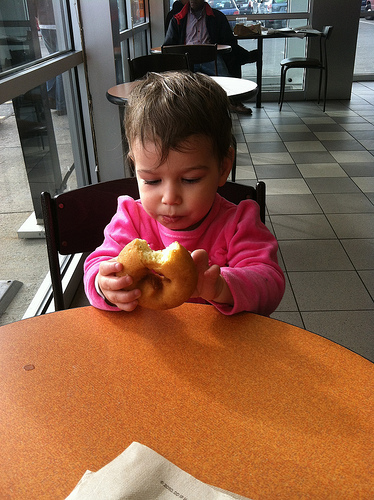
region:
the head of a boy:
[116, 88, 253, 234]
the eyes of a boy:
[135, 160, 234, 184]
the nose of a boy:
[160, 186, 188, 212]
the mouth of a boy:
[149, 206, 201, 229]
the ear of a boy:
[208, 116, 256, 197]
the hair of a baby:
[104, 4, 241, 225]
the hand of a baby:
[84, 241, 151, 320]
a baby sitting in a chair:
[74, 110, 348, 380]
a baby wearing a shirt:
[79, 125, 314, 345]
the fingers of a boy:
[95, 252, 152, 321]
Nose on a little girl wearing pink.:
[159, 177, 180, 206]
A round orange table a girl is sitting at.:
[1, 299, 373, 498]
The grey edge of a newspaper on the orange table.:
[63, 440, 247, 498]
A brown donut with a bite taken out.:
[112, 239, 195, 308]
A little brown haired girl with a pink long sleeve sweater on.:
[83, 72, 284, 317]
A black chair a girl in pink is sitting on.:
[39, 178, 266, 309]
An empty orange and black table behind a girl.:
[106, 74, 258, 106]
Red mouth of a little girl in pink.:
[157, 211, 185, 222]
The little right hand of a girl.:
[96, 259, 140, 313]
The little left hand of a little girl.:
[184, 248, 220, 299]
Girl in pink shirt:
[75, 60, 288, 322]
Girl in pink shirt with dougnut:
[76, 65, 280, 317]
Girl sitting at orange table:
[29, 65, 303, 357]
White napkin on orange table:
[54, 418, 262, 498]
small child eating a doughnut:
[77, 155, 236, 342]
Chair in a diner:
[270, 10, 344, 116]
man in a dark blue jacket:
[133, 1, 257, 62]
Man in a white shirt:
[158, 1, 238, 70]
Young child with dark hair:
[109, 67, 249, 236]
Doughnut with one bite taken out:
[103, 232, 204, 319]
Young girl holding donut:
[86, 69, 287, 317]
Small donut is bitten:
[113, 236, 193, 312]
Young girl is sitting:
[85, 71, 286, 316]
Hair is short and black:
[126, 68, 237, 180]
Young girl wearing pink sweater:
[81, 69, 286, 315]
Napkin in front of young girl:
[59, 440, 242, 498]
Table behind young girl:
[105, 78, 257, 105]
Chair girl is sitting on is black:
[37, 172, 269, 306]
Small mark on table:
[21, 360, 35, 376]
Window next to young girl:
[0, 0, 94, 325]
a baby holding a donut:
[84, 63, 296, 328]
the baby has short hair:
[70, 52, 312, 323]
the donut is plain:
[108, 237, 214, 317]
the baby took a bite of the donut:
[79, 49, 250, 326]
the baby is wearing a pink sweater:
[78, 181, 327, 349]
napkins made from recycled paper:
[66, 434, 246, 498]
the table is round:
[1, 296, 371, 497]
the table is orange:
[1, 298, 371, 491]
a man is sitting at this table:
[150, 0, 254, 66]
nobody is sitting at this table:
[99, 61, 299, 106]